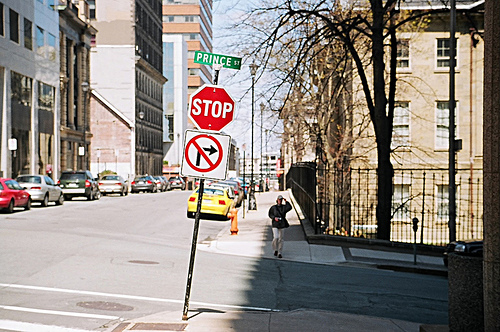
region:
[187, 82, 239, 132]
red stop sign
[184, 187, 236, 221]
yellow car parked on side of street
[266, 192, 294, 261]
person walking near intersection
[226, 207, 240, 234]
orange fire hydrant near corner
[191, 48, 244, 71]
green street sign above stop sign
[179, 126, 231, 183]
sign with an arrow and cross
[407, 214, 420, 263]
parking meter to right of perso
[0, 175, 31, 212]
red car parked on side of street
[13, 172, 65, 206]
silver car parked in front of red one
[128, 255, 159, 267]
man hold cover in middle of intersection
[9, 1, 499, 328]
Outside photo, taken during day.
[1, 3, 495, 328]
Urban area exterior, showing intersection and streets, during low traffic time.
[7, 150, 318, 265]
Cars lining both sides of city street, along curbs.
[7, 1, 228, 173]
Tall building facades, abutting curb.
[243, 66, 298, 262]
Tall street light, curb and pedestrian, nearing intersection.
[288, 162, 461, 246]
Black, metal fence, abutting property with flowers.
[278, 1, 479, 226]
Bare trees, tan building with windows.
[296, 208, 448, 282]
Down-sloping sidewalk and parking meter.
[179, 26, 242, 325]
Slanting, metal pole with multiple signs.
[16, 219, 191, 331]
Weathered street with white crosswalk lines.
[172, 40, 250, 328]
a pole with road signs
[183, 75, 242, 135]
a red octagonal stop sign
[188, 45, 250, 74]
a road sign that reads PRINCE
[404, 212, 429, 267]
a roadside parking meter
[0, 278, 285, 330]
white lines indicating a cross walk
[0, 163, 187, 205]
a row of parked cars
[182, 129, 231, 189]
a sign indicating no right turns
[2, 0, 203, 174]
tall city buildings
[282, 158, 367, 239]
black iron fence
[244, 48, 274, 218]
a tall road side light pole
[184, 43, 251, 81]
green and white sign on a pole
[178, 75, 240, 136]
red and white sign on a pole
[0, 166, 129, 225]
vehicles parked on a street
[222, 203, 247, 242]
fire hydrant on a sidewalk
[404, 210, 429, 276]
parking meter on a sidewalk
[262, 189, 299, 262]
person with a hat walking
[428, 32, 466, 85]
window on a building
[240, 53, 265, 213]
street light on a sidewalk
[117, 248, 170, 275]
manhole cover in a street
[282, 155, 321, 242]
fence near a sidewalk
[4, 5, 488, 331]
Exterior shot, daytime.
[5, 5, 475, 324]
Sunlit, urban area, showing intersection.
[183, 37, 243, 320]
Leaning metal pole. with street sign, stop sign and turn sign.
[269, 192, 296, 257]
Pedestrian in black and white, approaching intersection.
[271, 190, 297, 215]
Person, with hand near head, apparently gazing right.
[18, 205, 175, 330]
Weathered grey asphalt with drain covers and white, faded lines.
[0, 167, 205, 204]
Row of parked cars in sunlight.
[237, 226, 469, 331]
Shadowed side-street with curbs.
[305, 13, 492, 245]
Bare trees with tan building and black, exterior fence.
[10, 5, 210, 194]
Row of tall trees, alongside street.